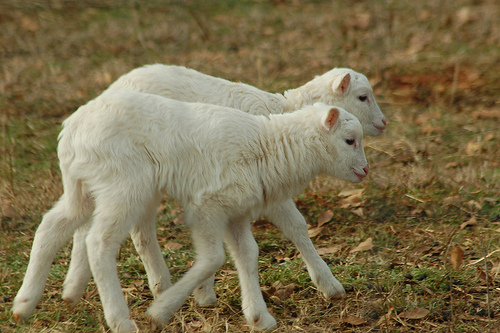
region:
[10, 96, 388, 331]
a small white sheep.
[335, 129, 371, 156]
the right eye of a small sheep.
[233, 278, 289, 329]
a left sheep paw.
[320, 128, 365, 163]
a sheep's right eye.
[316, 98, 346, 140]
the right ear of a sleep.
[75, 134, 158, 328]
a sheep's right butt cheek.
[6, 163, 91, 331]
the left hind leg of a sheep.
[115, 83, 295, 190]
the body of a sheep.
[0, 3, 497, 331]
a field of grass.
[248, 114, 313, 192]
a sheep's throat.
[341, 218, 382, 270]
leaf of the grass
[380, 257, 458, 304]
clump of green grass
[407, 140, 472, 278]
field lambs are in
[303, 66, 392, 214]
lambs heads against grass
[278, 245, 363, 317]
foot of the lamb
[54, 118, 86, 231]
tail of the lamb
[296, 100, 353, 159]
ear of the lamb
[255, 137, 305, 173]
fur on the lamb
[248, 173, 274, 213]
crease in the lambs fur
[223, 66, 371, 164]
one lamb behind the other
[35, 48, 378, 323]
the lamb is white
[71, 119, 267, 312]
the lamb is white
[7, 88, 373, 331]
The nearest of the two lambs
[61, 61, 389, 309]
The further of the two lambs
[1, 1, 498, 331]
The grass field the lambs are in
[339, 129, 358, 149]
The right eye of the nearest lamb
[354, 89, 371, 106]
The eye of the furthest lamb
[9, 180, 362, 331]
The legs of the lambs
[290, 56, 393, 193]
The heads of the lambs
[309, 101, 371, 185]
The head of the nearest lamb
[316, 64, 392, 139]
The head of the furthest lamb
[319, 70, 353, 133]
The ears of the lambs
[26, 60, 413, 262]
two animals next to each other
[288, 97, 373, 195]
head of the animal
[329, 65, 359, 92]
ear of the animal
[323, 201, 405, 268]
leaves on the grass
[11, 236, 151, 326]
back legs of the animal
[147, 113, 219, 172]
fur on the animal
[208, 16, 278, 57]
blurry ground in background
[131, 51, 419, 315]
two animals facing the right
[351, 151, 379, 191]
snout of the animal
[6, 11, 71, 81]
blurry background of the photo